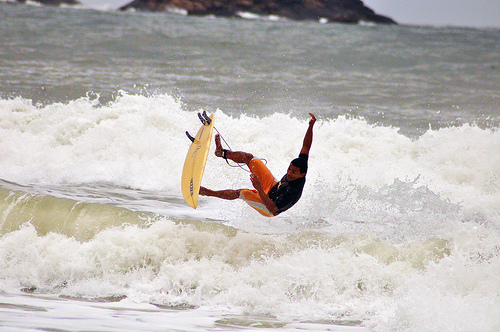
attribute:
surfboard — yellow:
[177, 109, 224, 217]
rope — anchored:
[205, 121, 267, 174]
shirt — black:
[274, 184, 310, 210]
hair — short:
[290, 157, 307, 172]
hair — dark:
[172, 110, 214, 211]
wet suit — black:
[262, 147, 312, 216]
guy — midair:
[198, 97, 325, 226]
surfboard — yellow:
[182, 111, 215, 209]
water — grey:
[0, 4, 495, 330]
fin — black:
[198, 107, 211, 124]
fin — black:
[183, 129, 196, 144]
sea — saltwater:
[195, 19, 417, 96]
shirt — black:
[270, 154, 309, 216]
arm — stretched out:
[300, 111, 317, 169]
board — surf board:
[182, 109, 216, 211]